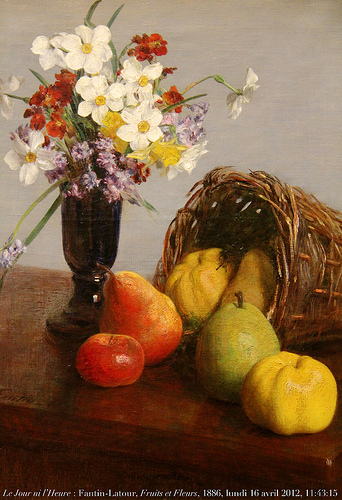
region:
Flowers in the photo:
[29, 66, 173, 167]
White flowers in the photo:
[60, 30, 150, 132]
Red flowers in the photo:
[139, 27, 190, 107]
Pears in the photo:
[205, 269, 263, 438]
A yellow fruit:
[243, 348, 338, 437]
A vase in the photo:
[57, 189, 125, 330]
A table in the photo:
[113, 402, 201, 444]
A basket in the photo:
[281, 202, 333, 331]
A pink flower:
[79, 150, 130, 202]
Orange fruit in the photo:
[68, 274, 184, 393]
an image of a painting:
[0, 1, 339, 496]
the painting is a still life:
[0, 0, 338, 497]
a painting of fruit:
[76, 246, 333, 436]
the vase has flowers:
[0, 0, 259, 213]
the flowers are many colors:
[4, 0, 260, 212]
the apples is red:
[80, 334, 139, 383]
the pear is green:
[192, 298, 274, 393]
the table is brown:
[0, 261, 339, 497]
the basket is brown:
[157, 167, 339, 356]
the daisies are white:
[1, 25, 257, 182]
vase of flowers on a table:
[20, 14, 286, 309]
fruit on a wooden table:
[77, 232, 327, 435]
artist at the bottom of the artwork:
[4, 483, 341, 498]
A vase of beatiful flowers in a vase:
[18, 21, 260, 246]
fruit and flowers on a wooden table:
[19, 27, 315, 448]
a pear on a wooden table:
[89, 252, 176, 357]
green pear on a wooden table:
[206, 294, 275, 395]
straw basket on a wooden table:
[190, 155, 332, 341]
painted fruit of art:
[245, 339, 334, 445]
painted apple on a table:
[69, 326, 154, 386]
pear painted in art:
[99, 264, 187, 365]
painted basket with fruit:
[148, 135, 336, 349]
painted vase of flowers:
[7, 24, 186, 333]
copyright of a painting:
[3, 483, 340, 499]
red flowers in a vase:
[31, 80, 79, 140]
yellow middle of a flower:
[135, 118, 151, 132]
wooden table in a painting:
[1, 274, 55, 418]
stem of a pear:
[229, 289, 250, 309]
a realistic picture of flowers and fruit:
[0, 3, 341, 488]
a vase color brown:
[46, 182, 126, 353]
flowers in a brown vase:
[2, 5, 257, 284]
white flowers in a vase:
[69, 54, 154, 113]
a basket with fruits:
[142, 158, 340, 354]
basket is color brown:
[163, 164, 340, 349]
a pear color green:
[185, 281, 280, 397]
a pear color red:
[93, 257, 186, 372]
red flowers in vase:
[119, 26, 170, 64]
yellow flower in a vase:
[137, 139, 185, 176]